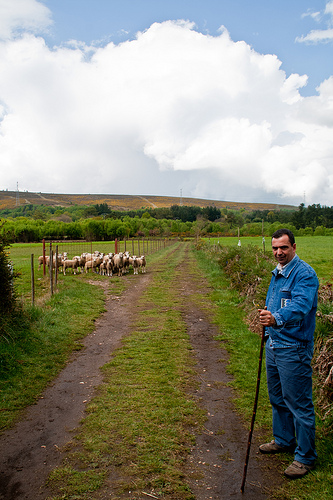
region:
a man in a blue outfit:
[257, 229, 318, 476]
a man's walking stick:
[238, 305, 267, 492]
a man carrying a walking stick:
[242, 228, 319, 488]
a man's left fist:
[256, 307, 275, 326]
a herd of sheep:
[38, 249, 146, 274]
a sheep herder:
[238, 227, 318, 491]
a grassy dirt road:
[0, 241, 271, 498]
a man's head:
[269, 228, 298, 264]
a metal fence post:
[29, 253, 36, 305]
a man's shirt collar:
[270, 261, 300, 276]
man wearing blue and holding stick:
[216, 226, 316, 401]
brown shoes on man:
[249, 428, 315, 490]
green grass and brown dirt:
[66, 363, 217, 446]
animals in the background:
[43, 223, 160, 311]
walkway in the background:
[132, 194, 166, 217]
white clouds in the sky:
[158, 149, 203, 178]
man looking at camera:
[252, 221, 304, 279]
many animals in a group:
[54, 231, 161, 281]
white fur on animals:
[125, 245, 149, 271]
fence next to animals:
[34, 231, 97, 295]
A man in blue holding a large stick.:
[224, 218, 322, 490]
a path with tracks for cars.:
[0, 238, 262, 490]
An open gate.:
[88, 239, 126, 271]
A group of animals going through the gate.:
[32, 248, 155, 286]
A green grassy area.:
[10, 234, 182, 280]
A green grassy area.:
[200, 231, 330, 279]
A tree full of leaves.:
[11, 213, 38, 239]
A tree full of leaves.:
[86, 218, 107, 241]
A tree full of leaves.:
[148, 218, 161, 233]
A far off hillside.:
[3, 190, 299, 210]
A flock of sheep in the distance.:
[32, 238, 156, 277]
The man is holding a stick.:
[232, 293, 280, 497]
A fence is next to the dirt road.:
[12, 234, 180, 293]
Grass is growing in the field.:
[302, 237, 330, 256]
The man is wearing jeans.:
[255, 341, 319, 462]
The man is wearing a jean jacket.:
[253, 257, 320, 351]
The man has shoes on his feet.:
[252, 422, 315, 485]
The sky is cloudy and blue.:
[21, 8, 329, 70]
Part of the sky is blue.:
[232, 2, 282, 25]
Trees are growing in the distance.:
[3, 199, 331, 229]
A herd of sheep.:
[39, 234, 159, 287]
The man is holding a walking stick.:
[197, 215, 324, 489]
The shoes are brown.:
[249, 426, 318, 490]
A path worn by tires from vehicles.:
[16, 223, 245, 474]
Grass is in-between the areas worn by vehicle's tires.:
[78, 282, 189, 491]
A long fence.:
[21, 222, 178, 311]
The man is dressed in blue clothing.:
[239, 223, 322, 474]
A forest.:
[13, 191, 325, 239]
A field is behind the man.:
[189, 194, 326, 300]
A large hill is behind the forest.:
[0, 185, 303, 239]